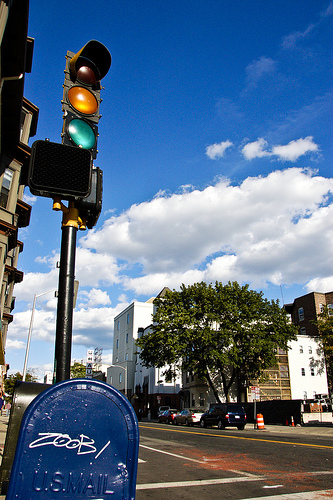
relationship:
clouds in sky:
[12, 135, 329, 354] [17, 2, 332, 376]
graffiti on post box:
[29, 430, 111, 462] [5, 380, 137, 497]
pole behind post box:
[54, 224, 77, 380] [5, 380, 137, 497]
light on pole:
[62, 41, 109, 151] [54, 224, 77, 380]